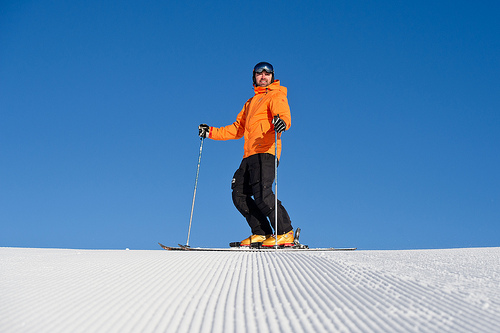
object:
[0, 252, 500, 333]
lines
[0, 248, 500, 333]
ground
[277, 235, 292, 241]
letter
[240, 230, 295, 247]
boots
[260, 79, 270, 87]
mustache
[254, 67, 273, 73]
goggles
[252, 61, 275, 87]
head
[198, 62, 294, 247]
he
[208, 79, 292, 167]
jacket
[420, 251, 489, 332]
wall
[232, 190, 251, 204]
knee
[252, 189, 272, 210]
knee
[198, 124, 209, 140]
glove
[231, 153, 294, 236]
pants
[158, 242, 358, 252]
skis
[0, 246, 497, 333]
snow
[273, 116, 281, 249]
ski pole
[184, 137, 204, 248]
ski pole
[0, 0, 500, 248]
sky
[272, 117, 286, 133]
glove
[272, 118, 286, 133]
hand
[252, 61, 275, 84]
hat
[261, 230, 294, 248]
shoe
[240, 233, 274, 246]
shoe